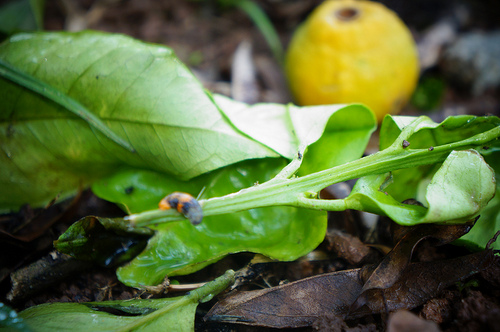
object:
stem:
[6, 251, 62, 305]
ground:
[175, 221, 260, 331]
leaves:
[0, 28, 500, 332]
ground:
[353, 262, 405, 312]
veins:
[109, 38, 177, 111]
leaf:
[0, 35, 23, 113]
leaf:
[463, 187, 499, 242]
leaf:
[279, 208, 322, 237]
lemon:
[282, 0, 422, 125]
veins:
[0, 30, 64, 72]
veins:
[15, 119, 204, 156]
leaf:
[227, 103, 280, 133]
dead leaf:
[201, 267, 368, 329]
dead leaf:
[342, 214, 480, 323]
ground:
[418, 276, 499, 331]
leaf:
[186, 227, 243, 248]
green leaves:
[0, 31, 500, 291]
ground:
[0, 0, 497, 67]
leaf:
[0, 169, 37, 215]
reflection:
[187, 77, 350, 180]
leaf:
[1, 31, 33, 52]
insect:
[158, 191, 203, 226]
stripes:
[158, 191, 194, 212]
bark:
[326, 229, 374, 266]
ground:
[2, 187, 72, 328]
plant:
[0, 0, 500, 332]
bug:
[123, 186, 135, 195]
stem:
[52, 215, 157, 269]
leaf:
[439, 115, 481, 146]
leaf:
[145, 305, 189, 315]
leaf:
[118, 262, 156, 282]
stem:
[116, 140, 464, 226]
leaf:
[7, 319, 96, 332]